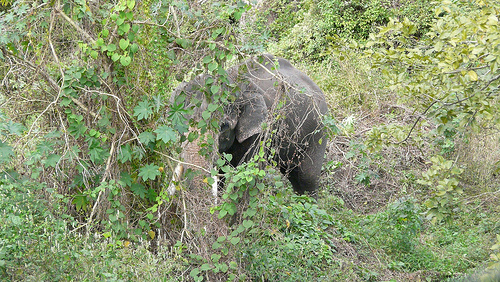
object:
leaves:
[133, 99, 157, 122]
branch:
[146, 147, 226, 176]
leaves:
[119, 55, 132, 66]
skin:
[281, 65, 303, 81]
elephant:
[163, 54, 335, 232]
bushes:
[0, 0, 499, 281]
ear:
[235, 91, 273, 143]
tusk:
[167, 163, 183, 198]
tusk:
[211, 164, 220, 209]